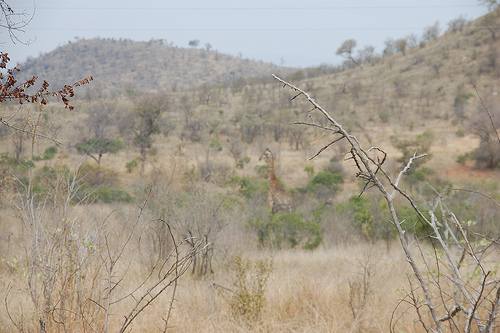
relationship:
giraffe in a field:
[260, 151, 297, 213] [2, 95, 499, 332]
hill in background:
[2, 39, 327, 98] [0, 0, 497, 98]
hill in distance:
[2, 39, 327, 98] [0, 2, 499, 98]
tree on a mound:
[274, 74, 499, 332] [318, 1, 496, 79]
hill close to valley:
[2, 39, 327, 98] [237, 58, 382, 97]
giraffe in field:
[260, 151, 297, 213] [2, 95, 499, 332]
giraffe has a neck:
[260, 151, 297, 213] [269, 158, 275, 183]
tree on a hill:
[274, 74, 499, 332] [2, 39, 327, 98]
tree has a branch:
[274, 74, 499, 332] [273, 76, 445, 333]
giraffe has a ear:
[260, 151, 297, 213] [265, 149, 271, 154]